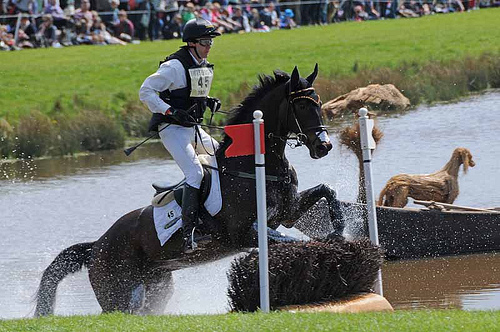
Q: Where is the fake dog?
A: In the water.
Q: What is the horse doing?
A: Jumping.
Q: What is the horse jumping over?
A: Gate.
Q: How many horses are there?
A: One.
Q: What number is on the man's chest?
A: 45.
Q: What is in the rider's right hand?
A: A crop.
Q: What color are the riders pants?
A: White.